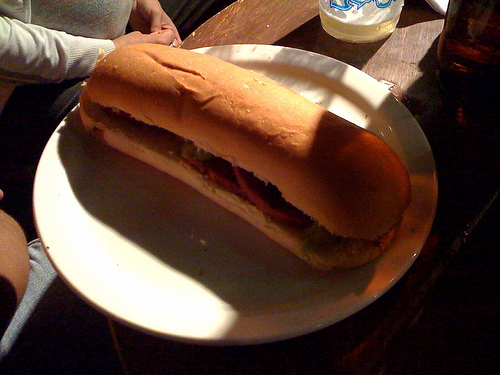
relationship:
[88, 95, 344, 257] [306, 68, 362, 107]
hot dog on plate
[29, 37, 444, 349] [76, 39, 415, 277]
plate under a sandwich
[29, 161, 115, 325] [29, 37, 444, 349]
light casted on plate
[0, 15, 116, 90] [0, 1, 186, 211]
arm of a man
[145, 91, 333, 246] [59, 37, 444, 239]
tomatoes in a sandwich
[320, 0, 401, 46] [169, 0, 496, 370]
cake on a table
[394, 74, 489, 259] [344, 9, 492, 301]
shadow on table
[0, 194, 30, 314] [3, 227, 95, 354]
elbow of a man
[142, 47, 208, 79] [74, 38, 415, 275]
crease in bread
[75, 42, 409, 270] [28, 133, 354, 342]
bun on a plate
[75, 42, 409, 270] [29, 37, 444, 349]
bun on a plate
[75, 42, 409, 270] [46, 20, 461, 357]
bun on a plate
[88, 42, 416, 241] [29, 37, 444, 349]
bun on a plate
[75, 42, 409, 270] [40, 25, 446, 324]
bun on a plate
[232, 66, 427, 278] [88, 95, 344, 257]
front portion of a hot dog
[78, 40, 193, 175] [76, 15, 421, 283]
back portion of a hot dog